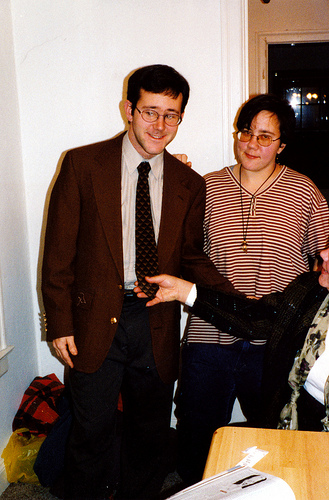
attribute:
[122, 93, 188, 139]
glasses — black rimmed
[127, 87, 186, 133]
glasses — black rimmed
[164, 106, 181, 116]
eyebrow — dark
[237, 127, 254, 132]
eyebrow — dark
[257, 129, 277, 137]
eyebrow — dark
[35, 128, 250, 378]
coat — brown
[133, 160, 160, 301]
tie — brown, black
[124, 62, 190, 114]
hair — black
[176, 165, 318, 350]
shirt — striped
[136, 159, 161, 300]
tie — black, red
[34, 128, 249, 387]
jacket — red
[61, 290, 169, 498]
pants — dark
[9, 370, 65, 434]
object — red and black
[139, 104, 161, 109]
eyebrow — dark